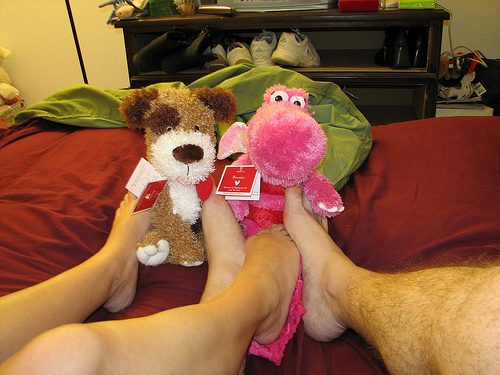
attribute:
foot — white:
[97, 192, 145, 312]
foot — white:
[194, 182, 247, 298]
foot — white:
[244, 225, 299, 346]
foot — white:
[284, 186, 349, 343]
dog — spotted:
[123, 84, 205, 270]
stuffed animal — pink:
[217, 83, 347, 238]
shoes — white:
[254, 33, 322, 72]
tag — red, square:
[223, 160, 259, 205]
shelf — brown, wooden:
[115, 26, 440, 119]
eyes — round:
[270, 91, 307, 108]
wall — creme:
[2, 2, 131, 107]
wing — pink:
[217, 122, 251, 161]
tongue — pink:
[174, 175, 192, 187]